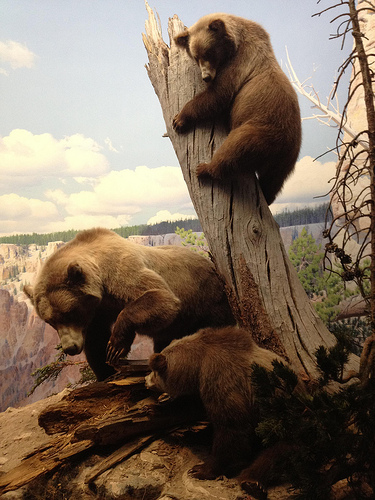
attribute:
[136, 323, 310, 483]
bear — brown 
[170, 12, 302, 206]
bear — brown 